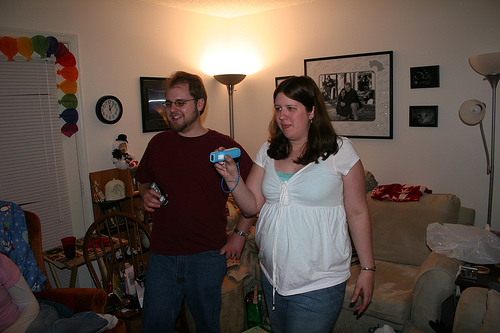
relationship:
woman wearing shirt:
[244, 66, 377, 333] [255, 148, 354, 292]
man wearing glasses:
[141, 74, 239, 301] [162, 100, 189, 109]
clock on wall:
[95, 95, 126, 126] [73, 12, 241, 108]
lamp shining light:
[215, 71, 247, 138] [195, 47, 264, 75]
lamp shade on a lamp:
[468, 50, 500, 76] [465, 52, 498, 198]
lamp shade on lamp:
[459, 102, 479, 127] [465, 52, 498, 198]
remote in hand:
[207, 151, 243, 161] [209, 146, 238, 184]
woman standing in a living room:
[244, 66, 377, 333] [3, 7, 498, 331]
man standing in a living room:
[141, 74, 239, 301] [3, 7, 498, 331]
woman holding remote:
[244, 66, 377, 333] [207, 151, 243, 161]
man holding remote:
[141, 74, 239, 301] [150, 183, 166, 204]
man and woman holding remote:
[141, 66, 378, 333] [207, 151, 243, 161]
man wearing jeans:
[141, 74, 239, 301] [146, 253, 224, 333]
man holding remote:
[141, 74, 239, 301] [207, 151, 243, 161]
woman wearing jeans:
[244, 66, 377, 333] [257, 271, 350, 332]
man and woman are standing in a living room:
[141, 66, 378, 333] [3, 7, 498, 331]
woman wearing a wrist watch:
[244, 66, 377, 333] [360, 265, 379, 274]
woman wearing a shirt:
[244, 66, 377, 333] [255, 148, 354, 292]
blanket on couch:
[373, 184, 426, 203] [363, 185, 460, 333]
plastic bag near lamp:
[428, 223, 498, 267] [465, 52, 498, 198]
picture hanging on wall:
[307, 56, 395, 139] [73, 12, 241, 108]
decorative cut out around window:
[3, 36, 75, 67] [3, 34, 87, 244]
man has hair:
[141, 74, 239, 301] [175, 71, 205, 98]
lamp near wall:
[215, 71, 247, 138] [73, 12, 241, 108]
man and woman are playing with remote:
[141, 66, 378, 333] [207, 151, 243, 161]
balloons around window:
[57, 57, 83, 136] [3, 34, 87, 244]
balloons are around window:
[57, 57, 83, 136] [3, 34, 87, 244]